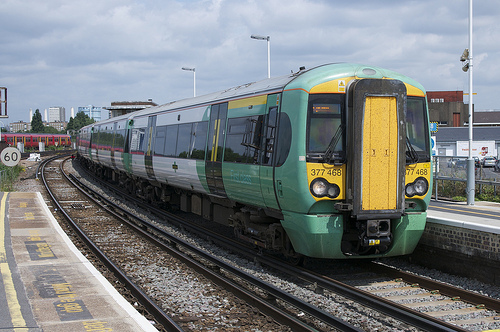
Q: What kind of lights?
A: Headlights.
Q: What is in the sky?
A: Clouds.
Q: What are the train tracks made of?
A: Metal.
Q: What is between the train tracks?
A: Gravel.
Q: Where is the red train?
A: In the distance.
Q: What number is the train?
A: 377468.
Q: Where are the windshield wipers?
A: On the front of the train.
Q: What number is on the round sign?
A: 60.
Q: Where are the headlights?
A: On the front of the train.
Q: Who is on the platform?
A: There are no people.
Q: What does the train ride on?
A: Tracks.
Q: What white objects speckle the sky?
A: Clouds.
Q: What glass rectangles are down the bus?
A: Windows.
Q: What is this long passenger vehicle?
A: Train.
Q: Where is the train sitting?
A: On the tracks.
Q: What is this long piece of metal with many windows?
A: Train.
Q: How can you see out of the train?
A: Windows.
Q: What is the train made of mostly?
A: Metal.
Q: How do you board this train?
A: Doors.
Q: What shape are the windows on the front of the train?
A: Rectangle.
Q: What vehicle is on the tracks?
A: Train.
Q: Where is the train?
A: On railroad tracks.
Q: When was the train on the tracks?
A: During daylight hours.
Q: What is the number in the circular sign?
A: 60.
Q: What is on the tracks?
A: A train.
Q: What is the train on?
A: Tracks.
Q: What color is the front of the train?
A: Green and yellow.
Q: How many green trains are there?
A: 1.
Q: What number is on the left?
A: 60.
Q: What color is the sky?
A: Blue.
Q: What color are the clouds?
A: White.